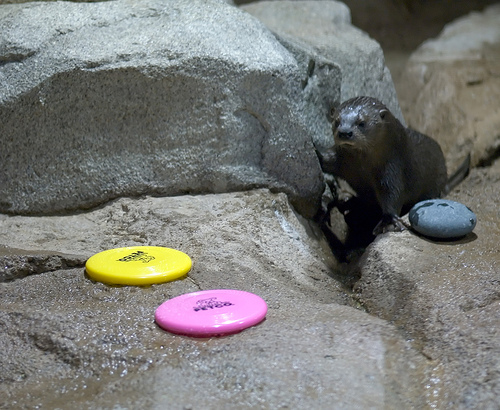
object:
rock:
[0, 0, 500, 410]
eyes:
[334, 120, 366, 128]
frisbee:
[84, 246, 195, 286]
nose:
[337, 129, 353, 138]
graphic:
[194, 297, 232, 311]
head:
[330, 96, 388, 150]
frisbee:
[154, 288, 267, 337]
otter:
[326, 94, 476, 249]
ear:
[379, 109, 387, 118]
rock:
[409, 198, 476, 238]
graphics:
[117, 251, 155, 263]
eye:
[358, 120, 366, 128]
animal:
[333, 96, 448, 236]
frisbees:
[84, 246, 268, 336]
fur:
[370, 162, 406, 200]